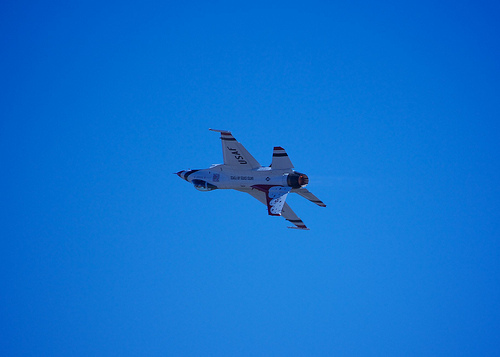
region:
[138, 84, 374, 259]
A fighter jet in flight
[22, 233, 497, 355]
The sky is blue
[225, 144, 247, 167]
Logo of U.S.A.F.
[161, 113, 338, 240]
A jet upside down in the air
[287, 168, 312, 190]
Flames from the tail of jet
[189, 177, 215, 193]
The pilot in the cockpit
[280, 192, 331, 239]
Stripes on the tale and wings.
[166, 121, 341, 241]
A white Jet with red, and blue designs.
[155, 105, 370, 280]
A jet doing tricks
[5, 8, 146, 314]
The sky is empty of clouds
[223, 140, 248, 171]
black letters on the plane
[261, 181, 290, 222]
the tail of the plane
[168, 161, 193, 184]
the nose of the plane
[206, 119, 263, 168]
the wing of the plane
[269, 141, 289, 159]
black stripes on the plane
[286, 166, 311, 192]
the afterburner on the plane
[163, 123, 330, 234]
a plane in the sky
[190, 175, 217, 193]
the cockpit of the plane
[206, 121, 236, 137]
the tip of the wing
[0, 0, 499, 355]
a clear blue sky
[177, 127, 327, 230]
a jet airplane flying upside down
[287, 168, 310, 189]
the jet engine of a jet plane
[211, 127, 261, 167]
right wing of a jet plane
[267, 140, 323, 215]
tail section of an air-force jet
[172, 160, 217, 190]
cockpit of a jet plane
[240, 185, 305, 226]
left wing of a jet plane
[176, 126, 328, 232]
an Air Force jet plane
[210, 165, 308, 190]
fuselage of an Air Force jet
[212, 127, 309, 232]
an Air Force jet's wingspan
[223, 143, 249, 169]
writing on a jet plane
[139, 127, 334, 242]
an airplane in the sky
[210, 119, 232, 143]
the blue stripes on the wing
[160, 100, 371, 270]
the plane is upside down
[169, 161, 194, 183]
stripes on the nose of the plane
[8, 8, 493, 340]
the sky is deep blue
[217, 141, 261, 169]
the letters USAF in blue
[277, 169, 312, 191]
the rear of the plane is black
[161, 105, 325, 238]
the plane is white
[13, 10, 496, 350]
big blue open sky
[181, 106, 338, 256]
flying air force jet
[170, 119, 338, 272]
upside down air force jet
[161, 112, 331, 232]
black striped wings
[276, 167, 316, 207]
black covered exhaust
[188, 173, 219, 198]
clear glass cock pit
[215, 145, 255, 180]
black USAF abbreviated letters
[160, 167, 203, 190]
black and white tip of fighter jet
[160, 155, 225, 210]
nose of fighter jet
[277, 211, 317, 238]
red and black wing stripes